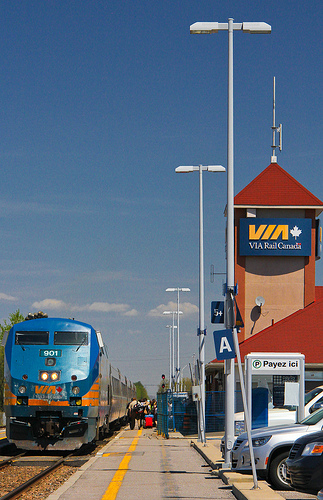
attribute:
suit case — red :
[145, 417, 151, 427]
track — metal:
[0, 451, 68, 498]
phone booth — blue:
[169, 390, 190, 431]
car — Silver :
[233, 405, 321, 481]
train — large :
[39, 316, 130, 477]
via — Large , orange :
[248, 222, 290, 239]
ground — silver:
[262, 102, 277, 125]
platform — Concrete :
[44, 416, 240, 497]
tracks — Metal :
[4, 453, 69, 499]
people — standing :
[123, 395, 160, 434]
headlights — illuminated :
[189, 21, 270, 33]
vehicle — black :
[287, 424, 322, 494]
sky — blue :
[11, 222, 190, 274]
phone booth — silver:
[241, 350, 303, 436]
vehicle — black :
[286, 430, 321, 489]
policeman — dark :
[121, 396, 140, 429]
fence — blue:
[155, 388, 266, 438]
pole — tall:
[164, 322, 179, 393]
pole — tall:
[161, 309, 183, 392]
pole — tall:
[164, 288, 192, 393]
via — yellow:
[248, 221, 290, 241]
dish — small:
[255, 294, 266, 307]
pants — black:
[128, 411, 136, 433]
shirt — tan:
[125, 400, 137, 411]